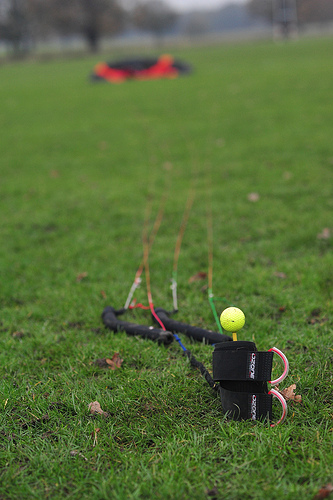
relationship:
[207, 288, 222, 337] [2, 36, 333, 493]
green strap on grass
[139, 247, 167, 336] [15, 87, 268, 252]
red strap on grass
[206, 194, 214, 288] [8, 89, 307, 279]
string on grass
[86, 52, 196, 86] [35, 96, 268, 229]
kite on grass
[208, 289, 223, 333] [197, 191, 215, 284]
green strap on string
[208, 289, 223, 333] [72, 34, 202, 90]
green strap on parachute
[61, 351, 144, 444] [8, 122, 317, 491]
leaves in grass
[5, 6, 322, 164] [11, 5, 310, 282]
focus in background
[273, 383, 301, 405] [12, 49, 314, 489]
leaf on grass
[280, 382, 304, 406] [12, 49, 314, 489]
leaf on grass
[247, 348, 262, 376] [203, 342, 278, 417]
brand name on stirrups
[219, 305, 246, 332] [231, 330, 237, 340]
ball on stick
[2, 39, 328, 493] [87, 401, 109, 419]
grass with leaves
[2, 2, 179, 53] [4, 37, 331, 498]
trees next to field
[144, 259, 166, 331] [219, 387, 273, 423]
red strap attached to cloth harness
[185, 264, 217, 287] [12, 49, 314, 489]
leaf on grass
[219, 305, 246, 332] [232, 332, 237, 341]
ball on stick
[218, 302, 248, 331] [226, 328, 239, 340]
ball atop stick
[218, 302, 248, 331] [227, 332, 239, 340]
ball stuck to stick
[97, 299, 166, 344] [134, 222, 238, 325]
handle with strings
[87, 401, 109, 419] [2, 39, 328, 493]
leaves in grass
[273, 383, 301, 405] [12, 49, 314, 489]
leaf in grass